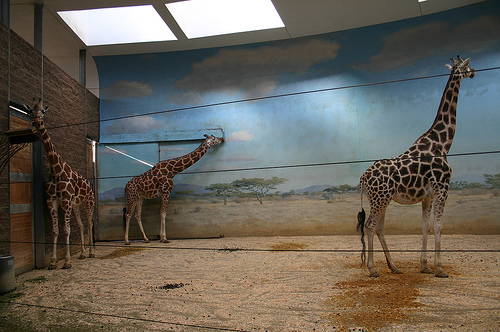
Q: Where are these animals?
A: Zoo.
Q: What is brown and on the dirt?
A: Poop.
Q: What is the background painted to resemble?
A: Savannah.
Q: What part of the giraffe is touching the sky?
A: Nose.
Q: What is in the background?
A: Savannah mural.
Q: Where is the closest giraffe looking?
A: Right.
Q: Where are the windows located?
A: Overhead.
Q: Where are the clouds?
A: On mural.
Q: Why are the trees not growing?
A: They are fake.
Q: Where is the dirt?
A: On the floor.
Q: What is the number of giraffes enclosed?
A: Three.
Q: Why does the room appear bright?
A: Sunlight.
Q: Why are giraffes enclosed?
A: Zoo.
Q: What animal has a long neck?
A: Giraffe.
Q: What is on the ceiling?
A: Sky lights.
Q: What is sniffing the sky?
A: Giraffe.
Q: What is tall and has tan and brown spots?
A: Giraffe.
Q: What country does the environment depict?
A: Africa.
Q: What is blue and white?
A: The sky.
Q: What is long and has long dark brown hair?
A: Giraffe's tail.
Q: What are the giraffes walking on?
A: Sand.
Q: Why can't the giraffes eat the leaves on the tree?
A: Its fake.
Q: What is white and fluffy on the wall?
A: Clouds.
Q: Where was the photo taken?
A: A Zoo.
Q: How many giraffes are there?
A: Three.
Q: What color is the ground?
A: Brown.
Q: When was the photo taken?
A: Daytime.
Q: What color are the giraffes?
A: Brown and Yellow.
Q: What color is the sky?
A: Blue.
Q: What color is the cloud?
A: White.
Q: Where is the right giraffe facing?
A: To the right.